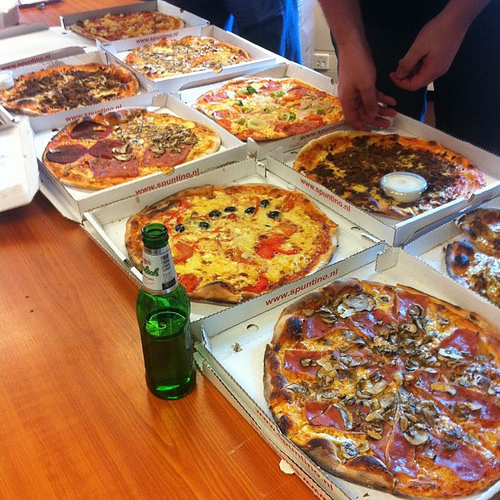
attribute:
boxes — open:
[16, 9, 491, 373]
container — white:
[385, 166, 426, 203]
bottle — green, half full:
[137, 227, 203, 411]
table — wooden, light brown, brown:
[12, 10, 372, 496]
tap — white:
[263, 453, 306, 485]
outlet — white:
[308, 47, 337, 72]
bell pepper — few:
[230, 74, 326, 129]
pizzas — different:
[19, 1, 493, 480]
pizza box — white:
[20, 119, 78, 237]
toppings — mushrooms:
[122, 106, 198, 166]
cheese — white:
[138, 41, 246, 66]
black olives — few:
[181, 189, 297, 221]